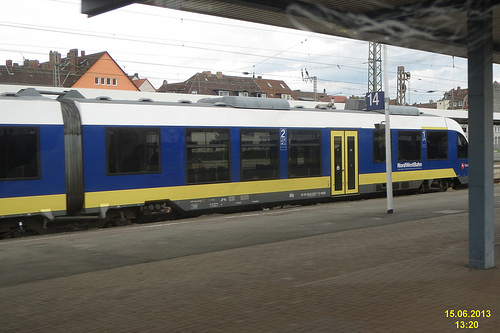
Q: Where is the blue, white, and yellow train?
A: At the station.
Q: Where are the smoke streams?
A: Upper right corner of photo.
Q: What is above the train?
A: Electrical wires.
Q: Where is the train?
A: At the train station.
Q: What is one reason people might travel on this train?
A: To visit another city.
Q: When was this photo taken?
A: Daytime.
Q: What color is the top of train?
A: White.